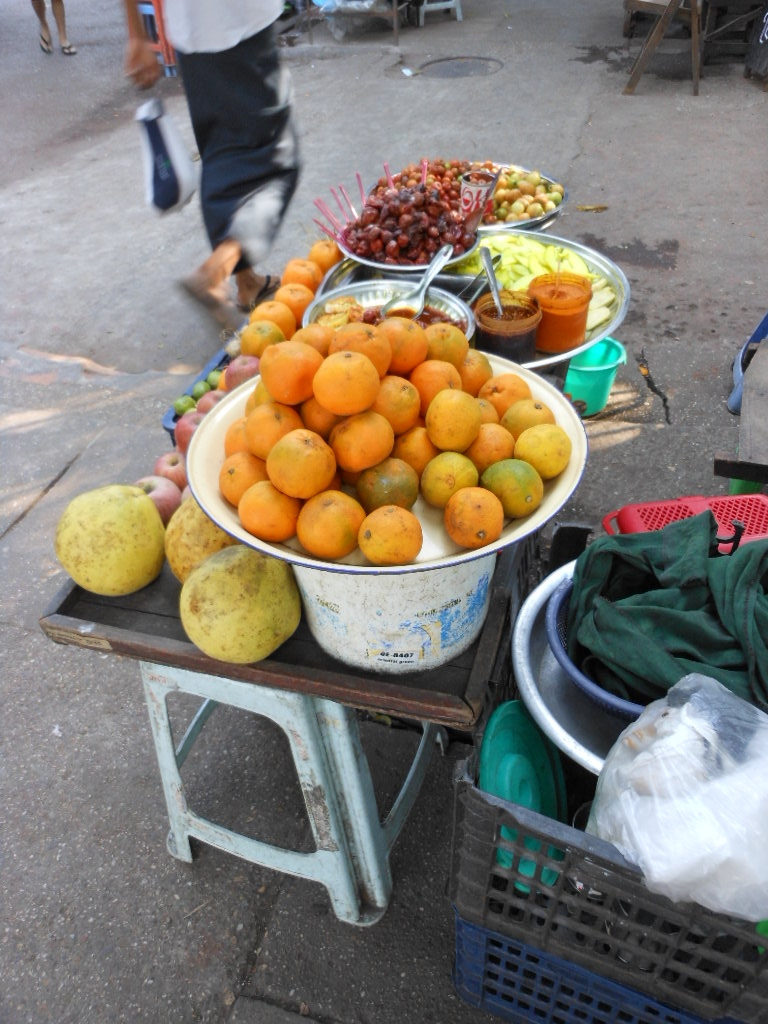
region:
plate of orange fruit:
[184, 316, 589, 574]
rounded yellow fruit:
[52, 483, 165, 597]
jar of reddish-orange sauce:
[527, 269, 591, 354]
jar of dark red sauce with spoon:
[473, 243, 539, 358]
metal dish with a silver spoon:
[301, 240, 472, 338]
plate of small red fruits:
[334, 183, 479, 267]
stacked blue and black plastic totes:
[447, 526, 766, 1018]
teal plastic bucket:
[566, 333, 627, 421]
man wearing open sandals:
[121, 1, 300, 334]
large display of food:
[40, 151, 637, 720]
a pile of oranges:
[224, 309, 579, 569]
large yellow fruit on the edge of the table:
[56, 467, 161, 605]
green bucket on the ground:
[563, 336, 629, 408]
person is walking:
[111, 1, 299, 322]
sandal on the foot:
[235, 264, 284, 308]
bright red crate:
[594, 474, 767, 556]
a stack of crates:
[451, 513, 766, 1014]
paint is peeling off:
[302, 778, 349, 859]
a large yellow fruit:
[46, 483, 153, 591]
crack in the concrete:
[0, 415, 123, 535]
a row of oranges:
[217, 212, 335, 344]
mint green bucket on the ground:
[569, 324, 637, 422]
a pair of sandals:
[28, 27, 89, 59]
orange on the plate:
[303, 486, 337, 548]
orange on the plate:
[382, 510, 424, 541]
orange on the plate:
[444, 467, 486, 495]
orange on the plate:
[422, 369, 469, 408]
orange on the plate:
[369, 456, 405, 488]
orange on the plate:
[427, 330, 462, 358]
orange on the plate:
[337, 318, 378, 367]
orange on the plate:
[526, 438, 591, 466]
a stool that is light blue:
[126, 660, 402, 940]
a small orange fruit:
[260, 433, 342, 491]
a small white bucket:
[276, 560, 496, 671]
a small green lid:
[479, 703, 561, 874]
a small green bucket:
[562, 337, 626, 414]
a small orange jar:
[535, 281, 590, 347]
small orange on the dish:
[366, 502, 410, 551]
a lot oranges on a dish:
[276, 350, 510, 522]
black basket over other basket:
[459, 842, 613, 920]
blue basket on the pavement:
[462, 930, 573, 1010]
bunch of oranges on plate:
[243, 276, 648, 604]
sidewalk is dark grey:
[368, 67, 509, 142]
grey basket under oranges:
[442, 752, 767, 1013]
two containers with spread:
[464, 248, 607, 367]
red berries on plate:
[305, 172, 511, 301]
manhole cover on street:
[391, 38, 502, 107]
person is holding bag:
[132, 67, 231, 254]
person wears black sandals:
[6, 18, 101, 71]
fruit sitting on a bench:
[57, 158, 636, 675]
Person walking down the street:
[109, 0, 296, 318]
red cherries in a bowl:
[304, 154, 494, 272]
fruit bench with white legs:
[47, 543, 520, 935]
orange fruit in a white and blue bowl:
[212, 312, 564, 568]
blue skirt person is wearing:
[174, 14, 310, 279]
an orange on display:
[375, 458, 392, 477]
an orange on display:
[363, 510, 421, 572]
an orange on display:
[444, 481, 480, 531]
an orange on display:
[270, 444, 322, 484]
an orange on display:
[340, 357, 395, 405]